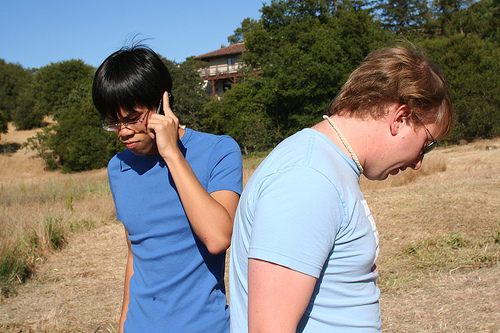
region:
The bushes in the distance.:
[1, 1, 498, 168]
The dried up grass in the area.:
[13, 123, 499, 326]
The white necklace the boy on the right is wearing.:
[319, 113, 369, 177]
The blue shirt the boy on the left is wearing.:
[111, 128, 248, 329]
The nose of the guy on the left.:
[117, 128, 134, 138]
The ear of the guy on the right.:
[390, 101, 409, 131]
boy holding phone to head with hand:
[90, 42, 240, 331]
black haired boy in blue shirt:
[93, 44, 243, 331]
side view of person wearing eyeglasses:
[228, 45, 451, 331]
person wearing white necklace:
[229, 42, 451, 331]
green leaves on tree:
[33, 60, 95, 114]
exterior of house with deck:
[196, 42, 271, 97]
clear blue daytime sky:
[0, 0, 272, 69]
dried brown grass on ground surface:
[0, 127, 499, 331]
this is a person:
[91, 38, 252, 331]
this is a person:
[220, 38, 455, 332]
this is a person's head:
[329, 17, 455, 189]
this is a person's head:
[77, 44, 187, 157]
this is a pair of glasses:
[99, 98, 179, 135]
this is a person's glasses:
[409, 100, 454, 167]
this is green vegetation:
[42, 97, 96, 169]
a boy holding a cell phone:
[103, 52, 187, 157]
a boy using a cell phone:
[145, 83, 182, 145]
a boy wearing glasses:
[414, 122, 450, 158]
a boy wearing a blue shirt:
[111, 117, 243, 329]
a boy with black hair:
[94, 45, 172, 123]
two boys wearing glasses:
[78, 50, 463, 162]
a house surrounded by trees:
[181, 15, 283, 132]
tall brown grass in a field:
[3, 170, 88, 283]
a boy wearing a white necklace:
[329, 104, 374, 186]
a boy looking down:
[357, 58, 462, 178]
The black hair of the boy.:
[94, 51, 174, 111]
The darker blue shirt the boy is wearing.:
[106, 139, 246, 331]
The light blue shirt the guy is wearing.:
[237, 128, 378, 332]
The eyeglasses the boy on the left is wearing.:
[94, 117, 151, 132]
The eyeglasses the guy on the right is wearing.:
[413, 117, 436, 156]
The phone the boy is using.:
[151, 83, 173, 115]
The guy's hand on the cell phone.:
[150, 88, 177, 155]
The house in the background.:
[178, 41, 254, 103]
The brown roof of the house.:
[190, 42, 252, 55]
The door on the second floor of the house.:
[229, 57, 236, 74]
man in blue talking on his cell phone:
[46, 18, 252, 330]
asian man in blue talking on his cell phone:
[58, 37, 252, 332]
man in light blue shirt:
[218, 23, 491, 331]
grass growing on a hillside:
[396, 228, 486, 298]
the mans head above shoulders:
[82, 29, 184, 158]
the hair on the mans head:
[89, 36, 184, 111]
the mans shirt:
[95, 129, 229, 331]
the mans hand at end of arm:
[135, 92, 197, 162]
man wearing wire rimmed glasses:
[100, 106, 150, 133]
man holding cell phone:
[158, 90, 174, 114]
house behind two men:
[190, 36, 275, 102]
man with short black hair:
[91, 29, 173, 127]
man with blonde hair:
[327, 38, 453, 141]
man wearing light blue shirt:
[106, 126, 244, 330]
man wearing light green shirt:
[228, 125, 382, 332]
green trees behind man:
[0, 0, 498, 175]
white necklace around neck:
[321, 112, 365, 176]